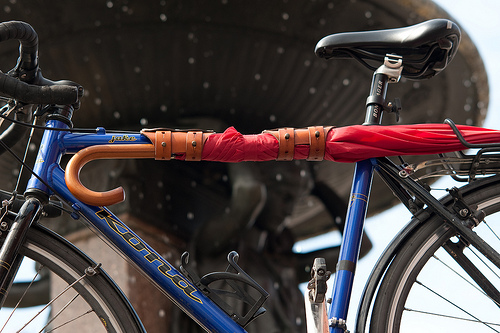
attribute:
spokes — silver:
[373, 202, 498, 332]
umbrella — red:
[138, 96, 422, 161]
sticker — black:
[85, 207, 211, 308]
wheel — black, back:
[352, 171, 499, 331]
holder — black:
[178, 248, 270, 325]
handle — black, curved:
[1, 16, 91, 118]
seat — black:
[298, 13, 468, 83]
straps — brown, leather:
[147, 123, 212, 171]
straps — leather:
[266, 127, 333, 161]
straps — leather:
[139, 128, 213, 160]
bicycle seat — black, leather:
[295, 12, 469, 78]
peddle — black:
[311, 256, 333, 303]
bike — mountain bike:
[2, 17, 499, 330]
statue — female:
[200, 164, 375, 296]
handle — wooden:
[63, 140, 158, 202]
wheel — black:
[4, 201, 151, 331]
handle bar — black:
[1, 17, 80, 102]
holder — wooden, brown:
[63, 143, 155, 207]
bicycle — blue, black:
[2, 19, 497, 327]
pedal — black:
[306, 256, 331, 306]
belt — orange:
[151, 127, 335, 166]